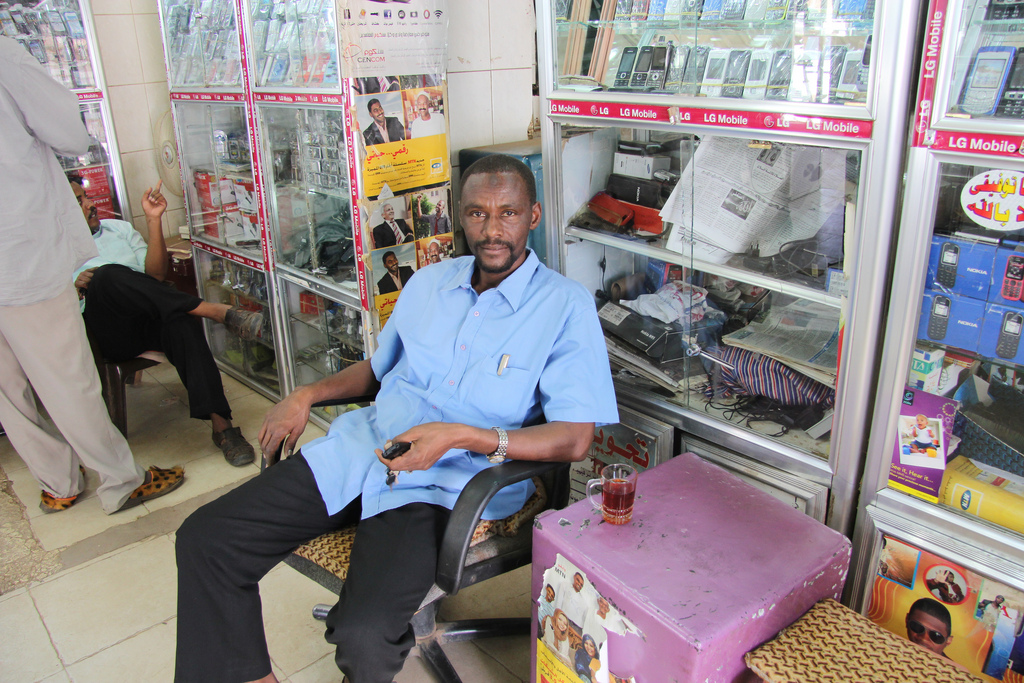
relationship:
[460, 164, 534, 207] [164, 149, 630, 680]
forehead of man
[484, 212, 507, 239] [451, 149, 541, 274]
nose of man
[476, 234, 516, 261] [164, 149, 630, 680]
mouth of man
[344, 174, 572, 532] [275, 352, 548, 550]
man in chair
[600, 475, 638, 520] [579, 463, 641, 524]
beverage in glass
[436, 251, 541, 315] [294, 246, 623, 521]
collar of shirt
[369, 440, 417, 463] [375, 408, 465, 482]
cell in hand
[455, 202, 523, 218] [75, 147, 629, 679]
eyebrows of man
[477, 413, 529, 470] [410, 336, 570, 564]
watch around wrist